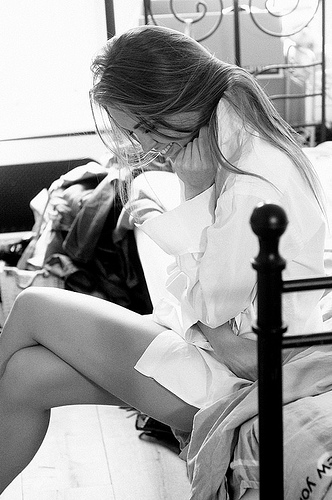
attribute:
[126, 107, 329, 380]
shirt — white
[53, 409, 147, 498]
floor — wooden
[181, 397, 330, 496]
sheets — for bed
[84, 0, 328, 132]
headboard — metal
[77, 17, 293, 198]
head — down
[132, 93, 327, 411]
shirt — white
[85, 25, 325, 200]
hair — long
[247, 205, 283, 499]
bed post — black, tubular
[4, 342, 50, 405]
knee —  woman's,  the  right 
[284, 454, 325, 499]
letters — black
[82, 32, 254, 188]
woman — sitting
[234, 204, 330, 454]
metal — black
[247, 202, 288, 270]
round part —  round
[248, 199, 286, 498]
bed post —  for bed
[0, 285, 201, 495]
legs — crossed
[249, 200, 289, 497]
post — black, metal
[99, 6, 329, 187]
bed frame — decorative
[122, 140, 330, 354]
sheets — white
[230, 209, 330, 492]
bed — metal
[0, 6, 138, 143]
light — bright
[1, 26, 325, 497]
woman — smiling, sitting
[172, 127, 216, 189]
hand —  the left,  woman's